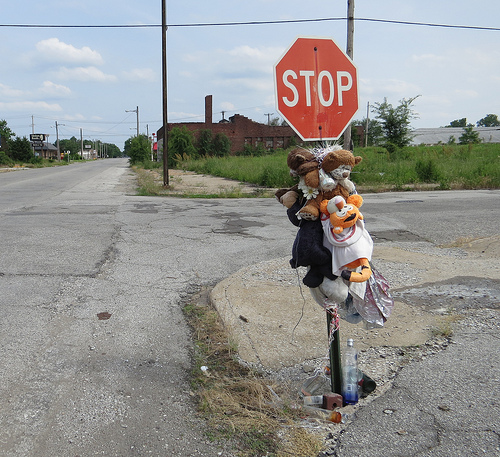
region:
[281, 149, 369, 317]
stuffed animals on sign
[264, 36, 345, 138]
red and white stop sign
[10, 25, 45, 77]
white clouds in blue sky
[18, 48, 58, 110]
white clouds in blue sky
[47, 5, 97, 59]
white clouds in blue sky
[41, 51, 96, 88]
white clouds in blue sky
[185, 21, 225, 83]
white clouds in blue sky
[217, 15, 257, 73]
white clouds in blue sky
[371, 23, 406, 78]
white clouds in blue sky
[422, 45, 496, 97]
white clouds in blue sky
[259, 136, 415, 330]
A bunch of stuffed animals on a stop sign.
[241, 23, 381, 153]
A rusting stop sign.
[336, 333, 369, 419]
An empty blue and clear bottle.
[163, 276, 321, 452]
Dying grass by a side walk.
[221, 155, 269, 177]
Green, thriving grass in the back ground.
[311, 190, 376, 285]
A dressed up Tiger doll.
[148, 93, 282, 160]
A building in the back ground.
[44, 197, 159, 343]
A cracking road in a ghost town.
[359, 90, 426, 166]
A big green tree in back ground.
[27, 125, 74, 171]
A business in the back ground.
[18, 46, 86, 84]
white clouds in blue sky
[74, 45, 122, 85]
white clouds in blue sky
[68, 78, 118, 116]
white clouds in blue sky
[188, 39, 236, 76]
white clouds in blue sky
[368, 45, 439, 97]
white clouds in blue sky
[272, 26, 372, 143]
white and red stop sign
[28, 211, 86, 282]
gray street pavement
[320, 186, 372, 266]
stuffed animals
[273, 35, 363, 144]
the stop sign is red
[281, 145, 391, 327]
stuffed animals hanging from pole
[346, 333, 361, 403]
a bottle left at pole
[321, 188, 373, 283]
tiger animal hanging from pole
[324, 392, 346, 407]
a brick is at base of pole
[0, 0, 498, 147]
the sky is cloudy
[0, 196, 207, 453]
the road is cracked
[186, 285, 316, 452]
grass grows by sidewalk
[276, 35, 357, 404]
sign is on corner of street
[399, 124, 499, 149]
building is white and rectangular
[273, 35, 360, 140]
A red and white sign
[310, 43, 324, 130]
a pair of rivets in a sign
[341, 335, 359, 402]
A bottle on the ground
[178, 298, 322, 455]
A small patch of grass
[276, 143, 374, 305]
some stuffed animals tied to a metal pole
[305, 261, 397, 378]
some deflated balloons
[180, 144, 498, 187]
A grassy landscape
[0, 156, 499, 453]
An asphalt road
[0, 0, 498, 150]
A clear blue sky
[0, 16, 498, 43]
A power line